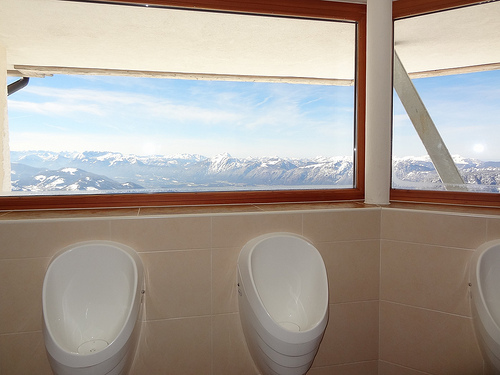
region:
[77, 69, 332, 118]
Sky is blue color.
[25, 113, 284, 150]
Clouds are white color.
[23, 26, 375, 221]
Window frame is brown color.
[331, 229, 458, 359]
Wall is brown color.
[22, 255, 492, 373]
Urinals are white color.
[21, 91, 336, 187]
Reflection is seen in mirror.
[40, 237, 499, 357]
Three urinals are seen.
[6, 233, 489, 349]
Urinals are attached to wall.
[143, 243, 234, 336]
Wall is made of tiles.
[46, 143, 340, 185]
Mountains are seen outside.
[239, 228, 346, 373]
a white urinal on the wall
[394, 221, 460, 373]
beige tile on the wall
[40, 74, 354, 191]
a window in the bathroom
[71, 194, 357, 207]
brown wood trim on the window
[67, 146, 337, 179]
snow capped mountains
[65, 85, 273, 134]
white clouds in the blue sky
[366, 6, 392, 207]
a beige panel on the wall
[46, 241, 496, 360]
white urinal is men's restroom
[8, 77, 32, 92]
a gray metal support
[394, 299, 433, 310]
white grout between the tiles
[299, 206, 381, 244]
a tan tile on the road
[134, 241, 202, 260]
a white crack in the wall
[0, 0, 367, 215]
a brown wooden window frame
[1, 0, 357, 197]
a glass window in the room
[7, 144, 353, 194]
a large mountain range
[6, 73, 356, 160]
a blue and white sky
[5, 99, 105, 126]
a white cloud in the sky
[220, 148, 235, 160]
the peak of a mountain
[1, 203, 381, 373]
a tan tile wall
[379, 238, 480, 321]
a tan brick in the wall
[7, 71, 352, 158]
a cloudy blue sky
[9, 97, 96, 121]
a white cloud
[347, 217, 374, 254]
part of a wall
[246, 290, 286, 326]
part of a toilet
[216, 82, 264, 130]
part of a cloud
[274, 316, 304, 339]
edge of a toilet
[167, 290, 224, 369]
part of a wall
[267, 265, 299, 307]
part of a toilet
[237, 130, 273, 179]
part of a hill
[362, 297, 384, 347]
part of a corner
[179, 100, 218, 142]
part of a window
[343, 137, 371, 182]
edge of a window